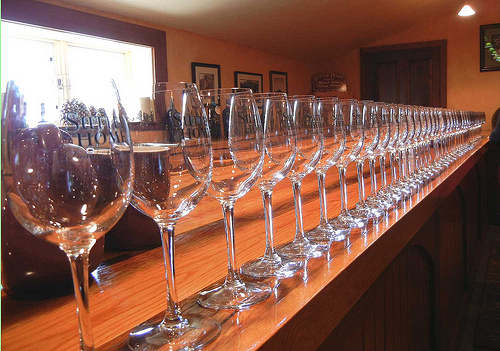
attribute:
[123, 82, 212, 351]
glass — clear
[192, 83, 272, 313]
glass — empty, clear, for wine, tall, stemmed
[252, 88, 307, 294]
glass — tall, empty, clear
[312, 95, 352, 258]
glass — stemmed, empty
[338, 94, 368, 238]
glass — empty, clear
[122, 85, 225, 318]
glass — empty, tall, clear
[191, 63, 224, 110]
print — black, hanging, framed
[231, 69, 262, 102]
print — framed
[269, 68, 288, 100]
print — framed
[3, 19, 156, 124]
window — bright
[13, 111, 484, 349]
counter — wood, wooden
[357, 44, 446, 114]
door — brown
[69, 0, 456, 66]
ceiling — white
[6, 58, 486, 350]
glasses — reflecting, based, stemmed, rowed, clear, clean, empty, lined up, straight, for wine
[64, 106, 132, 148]
words — written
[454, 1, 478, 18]
light — suspended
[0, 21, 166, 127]
sunlight — shining